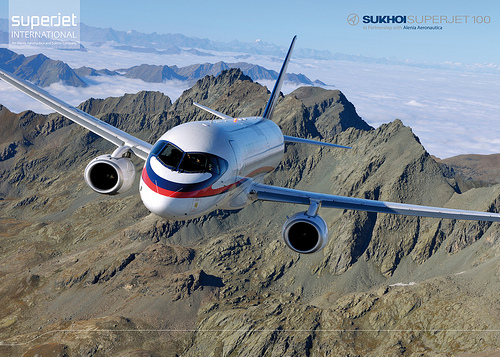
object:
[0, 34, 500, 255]
airplane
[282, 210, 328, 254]
engine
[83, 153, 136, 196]
engine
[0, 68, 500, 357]
mountain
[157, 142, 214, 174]
window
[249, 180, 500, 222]
wing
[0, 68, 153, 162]
wing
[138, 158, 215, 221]
nose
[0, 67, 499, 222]
distance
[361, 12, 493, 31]
lettering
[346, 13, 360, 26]
logo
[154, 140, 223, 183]
cockpit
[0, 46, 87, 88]
mountain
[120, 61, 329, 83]
mountain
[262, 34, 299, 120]
tail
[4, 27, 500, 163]
clouds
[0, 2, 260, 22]
sky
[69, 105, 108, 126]
logo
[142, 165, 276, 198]
stripes